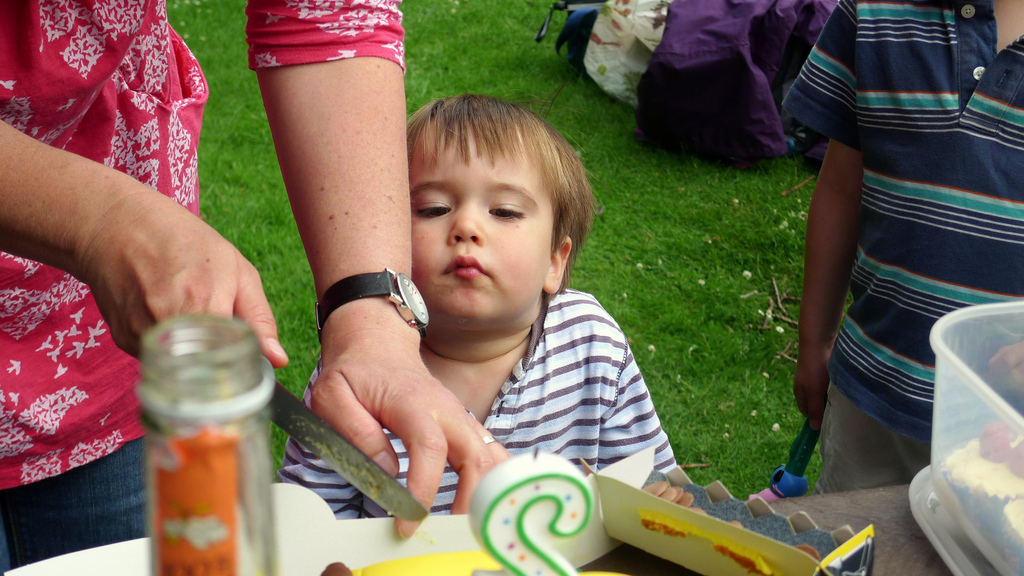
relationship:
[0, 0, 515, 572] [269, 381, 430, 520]
person holding butter knife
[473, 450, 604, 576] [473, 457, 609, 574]
candle on candle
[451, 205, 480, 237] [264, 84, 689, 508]
nose of boy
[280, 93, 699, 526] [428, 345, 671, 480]
boy wearing shirt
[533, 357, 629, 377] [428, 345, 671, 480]
stripe on shirt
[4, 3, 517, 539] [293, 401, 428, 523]
person holding knife